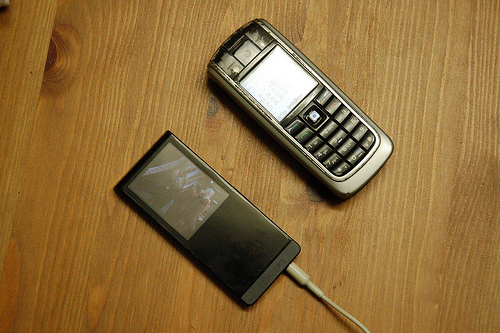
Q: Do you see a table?
A: Yes, there is a table.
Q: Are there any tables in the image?
A: Yes, there is a table.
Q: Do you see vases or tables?
A: Yes, there is a table.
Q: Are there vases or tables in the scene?
A: Yes, there is a table.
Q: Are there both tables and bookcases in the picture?
A: No, there is a table but no bookcases.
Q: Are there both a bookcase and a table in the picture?
A: No, there is a table but no bookcases.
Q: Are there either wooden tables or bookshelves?
A: Yes, there is a wood table.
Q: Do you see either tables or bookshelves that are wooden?
A: Yes, the table is wooden.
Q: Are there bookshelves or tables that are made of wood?
A: Yes, the table is made of wood.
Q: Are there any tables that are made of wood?
A: Yes, there is a table that is made of wood.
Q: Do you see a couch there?
A: No, there are no couches.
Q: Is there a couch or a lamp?
A: No, there are no couches or lamps.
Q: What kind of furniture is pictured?
A: The furniture is a table.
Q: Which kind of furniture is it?
A: The piece of furniture is a table.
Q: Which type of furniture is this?
A: This is a table.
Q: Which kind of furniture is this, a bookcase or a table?
A: This is a table.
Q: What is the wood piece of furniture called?
A: The piece of furniture is a table.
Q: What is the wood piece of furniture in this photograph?
A: The piece of furniture is a table.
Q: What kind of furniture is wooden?
A: The furniture is a table.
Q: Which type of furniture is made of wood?
A: The furniture is a table.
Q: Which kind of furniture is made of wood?
A: The furniture is a table.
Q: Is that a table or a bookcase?
A: That is a table.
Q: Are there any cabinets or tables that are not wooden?
A: No, there is a table but it is wooden.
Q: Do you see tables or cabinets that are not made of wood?
A: No, there is a table but it is made of wood.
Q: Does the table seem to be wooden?
A: Yes, the table is wooden.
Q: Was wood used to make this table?
A: Yes, the table is made of wood.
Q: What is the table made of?
A: The table is made of wood.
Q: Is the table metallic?
A: No, the table is wooden.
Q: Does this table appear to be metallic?
A: No, the table is wooden.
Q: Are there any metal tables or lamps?
A: No, there is a table but it is wooden.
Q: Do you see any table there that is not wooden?
A: No, there is a table but it is wooden.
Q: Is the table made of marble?
A: No, the table is made of wood.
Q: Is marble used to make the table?
A: No, the table is made of wood.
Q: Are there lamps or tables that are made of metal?
A: No, there is a table but it is made of wood.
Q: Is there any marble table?
A: No, there is a table but it is made of wood.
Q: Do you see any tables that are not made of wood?
A: No, there is a table but it is made of wood.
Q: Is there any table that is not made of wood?
A: No, there is a table but it is made of wood.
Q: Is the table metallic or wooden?
A: The table is wooden.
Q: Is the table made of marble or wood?
A: The table is made of wood.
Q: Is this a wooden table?
A: Yes, this is a wooden table.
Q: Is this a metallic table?
A: No, this is a wooden table.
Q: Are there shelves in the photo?
A: No, there are no shelves.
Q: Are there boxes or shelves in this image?
A: No, there are no shelves or boxes.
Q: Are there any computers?
A: No, there are no computers.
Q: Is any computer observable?
A: No, there are no computers.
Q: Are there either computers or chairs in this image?
A: No, there are no computers or chairs.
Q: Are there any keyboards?
A: Yes, there is a keyboard.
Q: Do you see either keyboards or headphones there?
A: Yes, there is a keyboard.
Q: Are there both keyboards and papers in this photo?
A: No, there is a keyboard but no papers.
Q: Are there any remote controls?
A: No, there are no remote controls.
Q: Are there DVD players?
A: No, there are no DVD players.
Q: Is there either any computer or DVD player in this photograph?
A: No, there are no DVD players or computers.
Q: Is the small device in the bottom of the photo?
A: Yes, the charger is in the bottom of the image.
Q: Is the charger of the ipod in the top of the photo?
A: No, the charger is in the bottom of the image.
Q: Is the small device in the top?
A: No, the charger is in the bottom of the image.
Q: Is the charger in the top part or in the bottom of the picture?
A: The charger is in the bottom of the image.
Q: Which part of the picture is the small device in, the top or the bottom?
A: The charger is in the bottom of the image.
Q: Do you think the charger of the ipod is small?
A: Yes, the charger is small.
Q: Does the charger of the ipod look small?
A: Yes, the charger is small.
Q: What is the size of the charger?
A: The charger is small.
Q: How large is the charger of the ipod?
A: The charger is small.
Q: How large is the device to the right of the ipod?
A: The charger is small.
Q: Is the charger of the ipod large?
A: No, the charger is small.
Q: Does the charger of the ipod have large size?
A: No, the charger is small.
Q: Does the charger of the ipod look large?
A: No, the charger is small.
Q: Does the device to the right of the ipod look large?
A: No, the charger is small.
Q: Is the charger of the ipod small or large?
A: The charger is small.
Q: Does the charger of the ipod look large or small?
A: The charger is small.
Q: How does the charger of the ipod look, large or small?
A: The charger is small.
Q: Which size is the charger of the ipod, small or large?
A: The charger is small.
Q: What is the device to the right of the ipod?
A: The device is a charger.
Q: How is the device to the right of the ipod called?
A: The device is a charger.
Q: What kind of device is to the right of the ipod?
A: The device is a charger.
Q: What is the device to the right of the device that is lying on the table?
A: The device is a charger.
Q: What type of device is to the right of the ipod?
A: The device is a charger.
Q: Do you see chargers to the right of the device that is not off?
A: Yes, there is a charger to the right of the ipod.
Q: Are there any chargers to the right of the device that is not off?
A: Yes, there is a charger to the right of the ipod.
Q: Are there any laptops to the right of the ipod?
A: No, there is a charger to the right of the ipod.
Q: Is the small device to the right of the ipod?
A: Yes, the charger is to the right of the ipod.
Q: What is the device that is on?
A: The device is an ipod.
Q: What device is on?
A: The device is an ipod.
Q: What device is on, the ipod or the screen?
A: The ipod is on.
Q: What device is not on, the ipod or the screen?
A: The screen is not on.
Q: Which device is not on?
A: The device is a screen.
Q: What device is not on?
A: The device is a screen.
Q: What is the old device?
A: The device is an ipod.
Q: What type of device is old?
A: The device is an ipod.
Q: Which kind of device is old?
A: The device is an ipod.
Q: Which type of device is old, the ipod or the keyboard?
A: The ipod is old.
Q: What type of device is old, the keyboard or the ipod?
A: The ipod is old.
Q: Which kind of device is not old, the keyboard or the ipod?
A: The keyboard is not old.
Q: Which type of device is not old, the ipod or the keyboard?
A: The keyboard is not old.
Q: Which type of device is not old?
A: The device is a keyboard.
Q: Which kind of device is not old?
A: The device is a keyboard.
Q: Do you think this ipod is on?
A: Yes, the ipod is on.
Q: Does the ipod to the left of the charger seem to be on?
A: Yes, the ipod is on.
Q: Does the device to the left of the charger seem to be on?
A: Yes, the ipod is on.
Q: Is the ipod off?
A: No, the ipod is on.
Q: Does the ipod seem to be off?
A: No, the ipod is on.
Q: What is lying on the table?
A: The ipod is lying on the table.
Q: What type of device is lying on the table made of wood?
A: The device is an ipod.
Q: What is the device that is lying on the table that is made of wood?
A: The device is an ipod.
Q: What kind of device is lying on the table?
A: The device is an ipod.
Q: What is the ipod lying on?
A: The ipod is lying on the table.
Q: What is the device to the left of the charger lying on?
A: The ipod is lying on the table.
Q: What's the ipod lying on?
A: The ipod is lying on the table.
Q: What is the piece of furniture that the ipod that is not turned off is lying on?
A: The piece of furniture is a table.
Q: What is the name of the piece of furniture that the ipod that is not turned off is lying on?
A: The piece of furniture is a table.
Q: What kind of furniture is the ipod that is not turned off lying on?
A: The ipod is lying on the table.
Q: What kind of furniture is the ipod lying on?
A: The ipod is lying on the table.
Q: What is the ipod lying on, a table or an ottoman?
A: The ipod is lying on a table.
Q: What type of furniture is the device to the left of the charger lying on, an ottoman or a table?
A: The ipod is lying on a table.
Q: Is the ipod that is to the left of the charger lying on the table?
A: Yes, the ipod is lying on the table.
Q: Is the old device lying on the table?
A: Yes, the ipod is lying on the table.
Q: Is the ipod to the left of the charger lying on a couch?
A: No, the ipod is lying on the table.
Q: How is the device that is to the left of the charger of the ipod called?
A: The device is an ipod.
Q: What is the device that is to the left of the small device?
A: The device is an ipod.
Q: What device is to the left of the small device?
A: The device is an ipod.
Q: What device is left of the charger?
A: The device is an ipod.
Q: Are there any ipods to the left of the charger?
A: Yes, there is an ipod to the left of the charger.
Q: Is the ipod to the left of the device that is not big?
A: Yes, the ipod is to the left of the charger.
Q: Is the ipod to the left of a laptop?
A: No, the ipod is to the left of the charger.